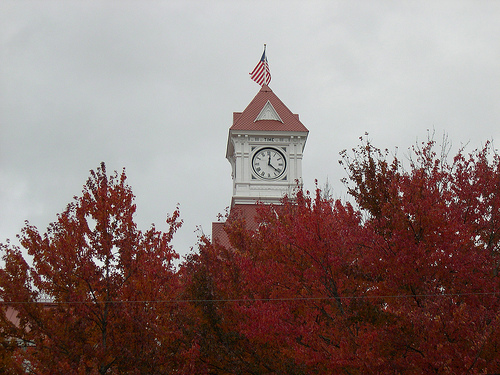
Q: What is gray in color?
A: The sky.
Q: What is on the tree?
A: Dark branches.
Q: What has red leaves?
A: The trees.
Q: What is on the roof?
A: A flag.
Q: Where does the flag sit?
A: On top of the tower.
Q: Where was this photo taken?
A: Outside, during the daytime.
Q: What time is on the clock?
A: 12:20.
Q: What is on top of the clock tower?
A: An American flag.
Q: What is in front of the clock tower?
A: Trees.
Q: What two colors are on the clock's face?
A: Black and white.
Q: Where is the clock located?
A: In a building tower.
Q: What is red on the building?
A: The roof.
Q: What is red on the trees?
A: The leaves.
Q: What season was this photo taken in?
A: Autumn.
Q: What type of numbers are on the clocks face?
A: Roman numerals.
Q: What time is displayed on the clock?
A: 12:21.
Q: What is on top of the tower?
A: A United States flag.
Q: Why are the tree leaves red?
A: The season is autumn.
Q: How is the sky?
A: Cloudy.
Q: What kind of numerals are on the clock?
A: Roman numerals.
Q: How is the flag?
A: The flag is waving.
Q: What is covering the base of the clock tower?
A: Trees.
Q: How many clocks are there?
A: 1.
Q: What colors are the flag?
A: Red, white, and blue.